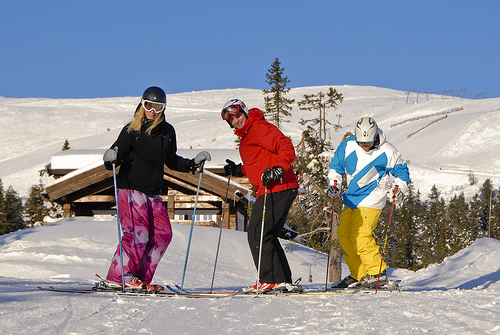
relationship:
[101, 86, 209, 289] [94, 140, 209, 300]
people standing on skis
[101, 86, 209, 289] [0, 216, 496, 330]
people skiing on hill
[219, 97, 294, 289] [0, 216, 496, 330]
people skiing on hill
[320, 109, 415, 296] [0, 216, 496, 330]
person skiing on hill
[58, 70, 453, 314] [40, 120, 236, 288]
skiers at ski resort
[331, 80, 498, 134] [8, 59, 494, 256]
ski lift going up mountain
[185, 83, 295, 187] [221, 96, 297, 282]
red jacket on skier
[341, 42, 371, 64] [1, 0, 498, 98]
clouds in blue sky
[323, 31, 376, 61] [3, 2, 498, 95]
clouds in sky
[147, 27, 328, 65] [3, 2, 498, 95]
clouds in sky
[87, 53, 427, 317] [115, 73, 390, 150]
people have on helmets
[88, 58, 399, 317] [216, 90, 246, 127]
people wearing goggles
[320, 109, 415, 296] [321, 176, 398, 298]
person holding ski poles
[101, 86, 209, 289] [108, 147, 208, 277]
people holding ski poles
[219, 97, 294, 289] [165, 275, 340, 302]
people on skis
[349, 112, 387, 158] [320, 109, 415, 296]
head on person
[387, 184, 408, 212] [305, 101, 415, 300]
hand on person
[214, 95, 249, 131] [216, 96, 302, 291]
head on person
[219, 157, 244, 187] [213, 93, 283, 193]
hand on person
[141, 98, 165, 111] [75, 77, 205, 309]
goggles on woman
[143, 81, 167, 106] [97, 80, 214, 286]
helmet on woman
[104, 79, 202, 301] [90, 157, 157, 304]
woman holding ski poles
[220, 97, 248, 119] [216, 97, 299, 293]
helmet on woman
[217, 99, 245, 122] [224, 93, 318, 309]
goggles on woman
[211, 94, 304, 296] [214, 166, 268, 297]
woman has poles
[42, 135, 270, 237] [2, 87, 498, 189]
house on hill